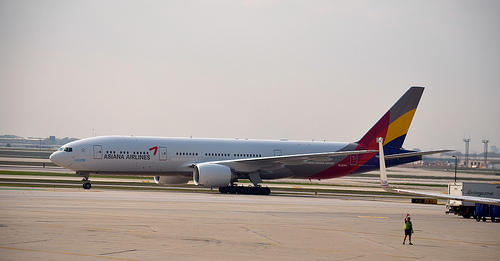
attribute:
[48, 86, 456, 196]
plane — large, white, commercial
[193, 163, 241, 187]
engine — large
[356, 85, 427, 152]
tail — multicolored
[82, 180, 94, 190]
wheel — down, black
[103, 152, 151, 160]
name — black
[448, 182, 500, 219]
truck — white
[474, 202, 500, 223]
cart — blue